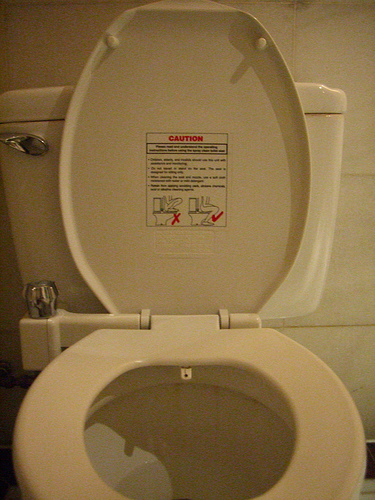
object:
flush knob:
[1, 132, 48, 154]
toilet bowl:
[84, 361, 294, 500]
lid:
[58, 0, 309, 314]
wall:
[0, 0, 375, 433]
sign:
[146, 132, 228, 228]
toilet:
[153, 197, 175, 224]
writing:
[168, 135, 202, 141]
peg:
[107, 36, 119, 48]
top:
[0, 82, 348, 315]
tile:
[294, 8, 374, 174]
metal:
[180, 368, 191, 379]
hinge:
[140, 308, 150, 329]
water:
[130, 468, 241, 491]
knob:
[21, 279, 58, 319]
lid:
[0, 81, 347, 125]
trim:
[333, 368, 365, 499]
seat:
[12, 325, 368, 500]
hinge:
[218, 309, 228, 329]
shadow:
[85, 383, 293, 498]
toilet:
[0, 0, 367, 500]